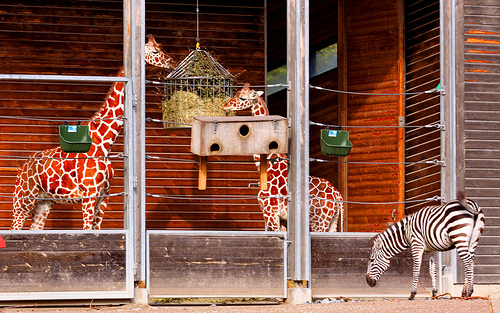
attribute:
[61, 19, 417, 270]
pen — giraffe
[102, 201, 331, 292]
divider — see through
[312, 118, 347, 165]
feeder — green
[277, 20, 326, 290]
post — tall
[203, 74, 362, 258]
giraffe — small, eating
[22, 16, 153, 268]
giraffe — tall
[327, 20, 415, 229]
wall — wood slats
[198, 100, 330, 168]
box — rectangular, holed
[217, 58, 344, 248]
giraffe — young, in cage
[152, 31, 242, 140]
feeder — hanging, hay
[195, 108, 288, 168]
holed box — wooden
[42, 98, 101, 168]
container — plastic, green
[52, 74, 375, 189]
containers — green, plastic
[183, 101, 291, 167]
box — wooden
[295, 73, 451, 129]
cable — metal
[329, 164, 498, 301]
zebra — outside enclosure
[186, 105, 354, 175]
wooden box — holed, rectangular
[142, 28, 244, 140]
wire basket — filled, domed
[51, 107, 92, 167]
container — green